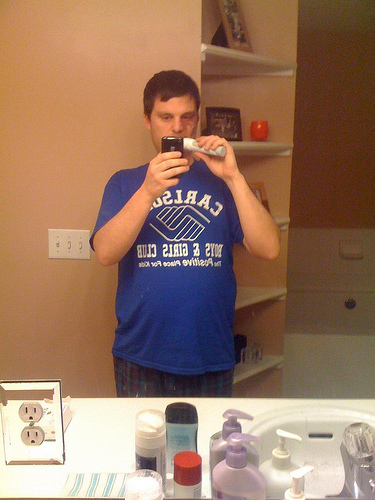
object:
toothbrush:
[181, 137, 231, 157]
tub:
[283, 325, 375, 404]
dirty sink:
[242, 405, 373, 495]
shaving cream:
[172, 446, 204, 494]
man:
[92, 68, 286, 393]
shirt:
[87, 159, 245, 377]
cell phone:
[160, 136, 184, 178]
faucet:
[321, 421, 374, 499]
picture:
[219, 1, 254, 53]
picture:
[208, 105, 241, 138]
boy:
[84, 62, 282, 395]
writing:
[135, 240, 231, 274]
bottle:
[170, 449, 204, 499]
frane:
[204, 103, 243, 139]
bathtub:
[90, 69, 283, 397]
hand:
[143, 150, 190, 187]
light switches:
[48, 228, 92, 261]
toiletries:
[117, 395, 320, 499]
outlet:
[0, 379, 65, 463]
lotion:
[211, 428, 274, 499]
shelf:
[200, 43, 298, 78]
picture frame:
[204, 105, 242, 142]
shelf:
[197, 129, 293, 157]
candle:
[250, 120, 269, 141]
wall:
[0, 1, 200, 394]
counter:
[0, 394, 375, 500]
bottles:
[163, 401, 200, 489]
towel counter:
[66, 468, 133, 500]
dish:
[57, 408, 158, 474]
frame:
[212, 2, 252, 52]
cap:
[174, 448, 202, 483]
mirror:
[0, 0, 373, 497]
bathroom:
[0, 2, 374, 497]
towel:
[54, 467, 132, 496]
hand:
[193, 134, 237, 184]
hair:
[142, 68, 203, 123]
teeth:
[167, 137, 190, 145]